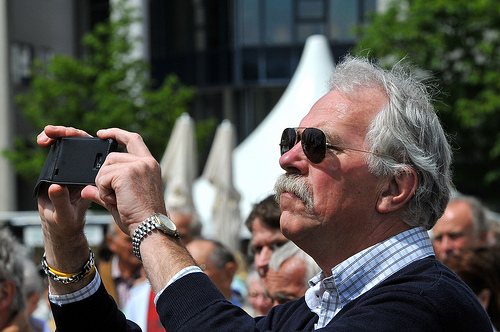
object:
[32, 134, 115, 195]
camera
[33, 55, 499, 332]
man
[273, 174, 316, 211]
mustache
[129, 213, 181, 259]
watch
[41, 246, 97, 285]
bracelet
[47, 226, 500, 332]
shirt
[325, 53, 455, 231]
hair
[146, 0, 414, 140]
building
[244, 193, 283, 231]
hair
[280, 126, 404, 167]
sunglasses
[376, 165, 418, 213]
ear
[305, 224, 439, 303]
collar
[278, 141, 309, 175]
nose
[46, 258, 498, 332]
sweater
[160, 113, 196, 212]
umbrella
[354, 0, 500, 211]
tree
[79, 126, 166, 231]
hands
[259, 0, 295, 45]
windows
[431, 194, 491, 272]
people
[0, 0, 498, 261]
distance